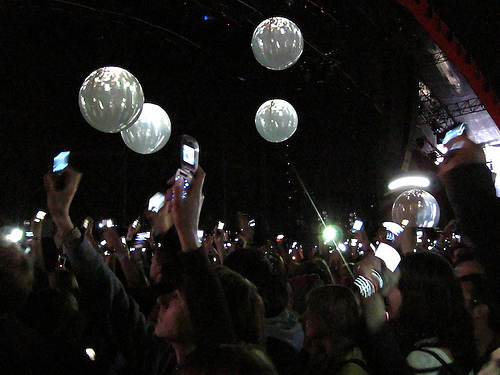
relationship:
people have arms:
[2, 166, 499, 374] [38, 163, 235, 253]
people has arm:
[2, 166, 499, 374] [173, 166, 230, 348]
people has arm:
[2, 166, 499, 374] [40, 166, 152, 359]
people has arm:
[2, 166, 499, 374] [436, 136, 496, 326]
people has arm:
[2, 166, 499, 374] [352, 245, 388, 335]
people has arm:
[2, 166, 499, 374] [100, 224, 151, 305]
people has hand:
[2, 166, 499, 374] [210, 225, 227, 253]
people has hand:
[2, 166, 499, 374] [165, 166, 209, 238]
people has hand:
[2, 166, 499, 374] [207, 230, 227, 252]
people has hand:
[2, 166, 499, 374] [235, 228, 252, 250]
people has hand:
[2, 166, 499, 374] [39, 167, 87, 222]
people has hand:
[2, 166, 499, 374] [96, 222, 119, 246]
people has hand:
[2, 166, 499, 374] [27, 209, 47, 231]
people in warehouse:
[2, 166, 499, 374] [6, 14, 498, 371]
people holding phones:
[2, 165, 499, 374] [130, 117, 267, 353]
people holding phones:
[2, 166, 499, 374] [0, 131, 212, 241]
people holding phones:
[2, 165, 499, 374] [47, 125, 204, 181]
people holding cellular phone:
[2, 166, 499, 374] [169, 135, 199, 201]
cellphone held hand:
[97, 213, 116, 240] [89, 197, 133, 264]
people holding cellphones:
[2, 166, 499, 374] [40, 123, 423, 244]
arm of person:
[44, 160, 159, 349] [37, 152, 269, 373]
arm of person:
[430, 112, 499, 358] [446, 134, 485, 348]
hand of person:
[165, 168, 207, 253] [165, 164, 272, 374]